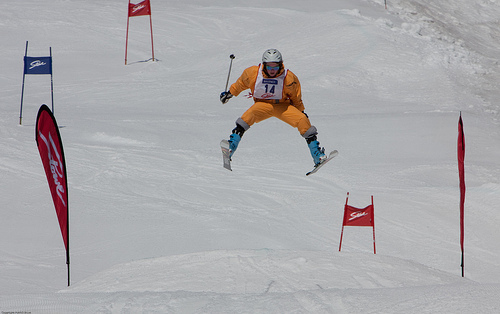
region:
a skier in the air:
[204, 34, 339, 186]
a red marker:
[336, 183, 382, 253]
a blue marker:
[15, 31, 62, 125]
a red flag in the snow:
[19, 96, 81, 283]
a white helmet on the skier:
[257, 47, 287, 65]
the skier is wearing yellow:
[232, 62, 309, 134]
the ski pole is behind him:
[221, 44, 236, 94]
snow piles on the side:
[382, 4, 487, 83]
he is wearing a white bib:
[257, 70, 282, 102]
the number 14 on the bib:
[262, 85, 278, 95]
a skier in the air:
[173, 25, 412, 213]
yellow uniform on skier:
[206, 34, 337, 150]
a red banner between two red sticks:
[308, 178, 427, 254]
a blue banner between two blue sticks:
[13, 33, 96, 150]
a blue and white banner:
[15, 45, 67, 88]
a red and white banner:
[321, 190, 392, 265]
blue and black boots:
[301, 126, 342, 178]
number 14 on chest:
[251, 72, 291, 102]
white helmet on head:
[258, 46, 290, 67]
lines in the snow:
[33, 122, 345, 309]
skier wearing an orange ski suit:
[214, 45, 342, 185]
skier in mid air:
[213, 43, 339, 184]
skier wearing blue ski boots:
[211, 39, 343, 183]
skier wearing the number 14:
[208, 41, 348, 185]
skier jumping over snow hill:
[205, 42, 340, 299]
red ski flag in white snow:
[336, 186, 387, 260]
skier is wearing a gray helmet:
[216, 42, 339, 187]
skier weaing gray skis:
[208, 43, 341, 187]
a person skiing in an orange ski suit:
[213, 44, 343, 181]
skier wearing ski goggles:
[211, 43, 344, 185]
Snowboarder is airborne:
[213, 46, 342, 176]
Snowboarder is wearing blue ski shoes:
[214, 120, 346, 167]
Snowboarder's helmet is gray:
[261, 47, 286, 65]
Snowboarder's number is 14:
[256, 74, 280, 100]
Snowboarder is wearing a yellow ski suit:
[230, 54, 320, 136]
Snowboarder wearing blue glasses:
[262, 64, 285, 71]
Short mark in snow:
[335, 186, 384, 256]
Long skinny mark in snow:
[453, 114, 470, 276]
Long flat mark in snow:
[23, 104, 78, 289]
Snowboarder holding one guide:
[223, 45, 238, 100]